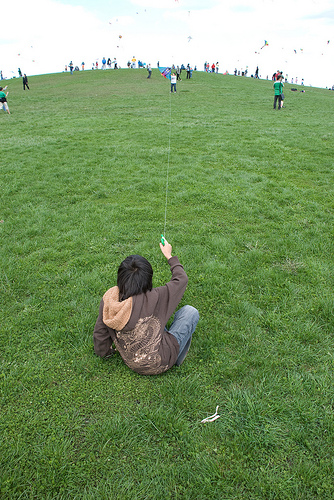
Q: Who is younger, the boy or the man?
A: The boy is younger than the man.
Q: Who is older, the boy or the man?
A: The man is older than the boy.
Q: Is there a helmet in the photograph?
A: No, there are no helmets.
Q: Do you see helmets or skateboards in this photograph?
A: No, there are no helmets or skateboards.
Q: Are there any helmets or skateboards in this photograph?
A: No, there are no helmets or skateboards.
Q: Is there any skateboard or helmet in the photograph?
A: No, there are no helmets or skateboards.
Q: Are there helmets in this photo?
A: No, there are no helmets.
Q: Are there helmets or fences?
A: No, there are no helmets or fences.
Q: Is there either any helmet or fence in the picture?
A: No, there are no helmets or fences.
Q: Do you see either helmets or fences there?
A: No, there are no helmets or fences.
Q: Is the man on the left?
A: Yes, the man is on the left of the image.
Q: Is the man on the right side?
A: No, the man is on the left of the image.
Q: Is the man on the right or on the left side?
A: The man is on the left of the image.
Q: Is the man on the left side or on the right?
A: The man is on the left of the image.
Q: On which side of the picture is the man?
A: The man is on the left of the image.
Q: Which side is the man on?
A: The man is on the left of the image.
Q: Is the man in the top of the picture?
A: Yes, the man is in the top of the image.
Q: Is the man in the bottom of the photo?
A: No, the man is in the top of the image.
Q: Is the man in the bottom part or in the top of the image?
A: The man is in the top of the image.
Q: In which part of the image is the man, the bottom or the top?
A: The man is in the top of the image.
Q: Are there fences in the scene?
A: No, there are no fences.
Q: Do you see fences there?
A: No, there are no fences.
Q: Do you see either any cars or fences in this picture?
A: No, there are no fences or cars.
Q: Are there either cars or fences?
A: No, there are no fences or cars.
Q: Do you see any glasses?
A: No, there are no glasses.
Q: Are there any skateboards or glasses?
A: No, there are no glasses or skateboards.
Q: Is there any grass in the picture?
A: Yes, there is grass.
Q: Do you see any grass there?
A: Yes, there is grass.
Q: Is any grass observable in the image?
A: Yes, there is grass.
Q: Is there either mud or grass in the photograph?
A: Yes, there is grass.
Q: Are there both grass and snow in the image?
A: No, there is grass but no snow.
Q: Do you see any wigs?
A: No, there are no wigs.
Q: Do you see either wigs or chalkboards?
A: No, there are no wigs or chalkboards.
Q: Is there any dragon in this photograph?
A: Yes, there is a dragon.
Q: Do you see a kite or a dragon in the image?
A: Yes, there is a dragon.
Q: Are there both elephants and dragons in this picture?
A: No, there is a dragon but no elephants.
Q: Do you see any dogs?
A: No, there are no dogs.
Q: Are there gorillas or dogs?
A: No, there are no dogs or gorillas.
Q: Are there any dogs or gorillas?
A: No, there are no dogs or gorillas.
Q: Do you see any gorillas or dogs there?
A: No, there are no dogs or gorillas.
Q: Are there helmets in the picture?
A: No, there are no helmets.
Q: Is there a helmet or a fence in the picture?
A: No, there are no helmets or fences.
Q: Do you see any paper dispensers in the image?
A: No, there are no paper dispensers.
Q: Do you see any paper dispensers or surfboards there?
A: No, there are no paper dispensers or surfboards.